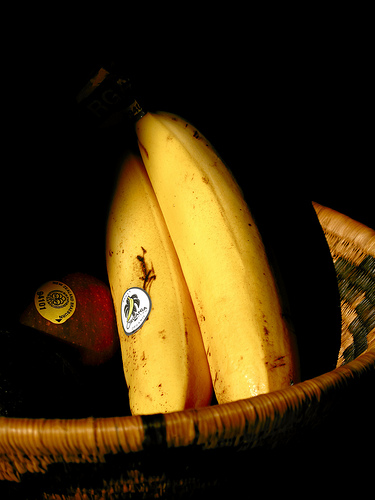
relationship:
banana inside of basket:
[107, 148, 212, 413] [15, 187, 372, 498]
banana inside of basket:
[107, 164, 197, 414] [15, 187, 372, 498]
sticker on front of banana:
[118, 286, 150, 332] [107, 164, 197, 414]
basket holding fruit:
[15, 187, 372, 498] [25, 72, 291, 394]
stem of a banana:
[86, 67, 153, 121] [107, 148, 212, 413]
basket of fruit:
[15, 187, 372, 498] [25, 72, 291, 394]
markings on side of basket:
[320, 236, 373, 366] [15, 187, 372, 498]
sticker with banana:
[118, 286, 150, 332] [107, 164, 197, 414]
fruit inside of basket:
[25, 72, 291, 394] [15, 187, 372, 498]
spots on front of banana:
[135, 245, 160, 300] [107, 164, 197, 414]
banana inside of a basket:
[107, 148, 212, 413] [15, 187, 372, 498]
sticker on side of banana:
[118, 286, 150, 332] [107, 164, 197, 414]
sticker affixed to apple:
[33, 280, 74, 325] [19, 272, 111, 370]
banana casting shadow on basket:
[107, 148, 212, 413] [15, 187, 372, 498]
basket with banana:
[15, 187, 372, 498] [107, 148, 212, 413]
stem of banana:
[86, 67, 153, 121] [107, 148, 212, 413]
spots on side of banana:
[135, 245, 160, 300] [107, 148, 212, 413]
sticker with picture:
[118, 286, 150, 332] [122, 297, 140, 319]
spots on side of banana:
[135, 245, 160, 300] [107, 164, 197, 414]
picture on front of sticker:
[122, 297, 140, 319] [118, 286, 150, 332]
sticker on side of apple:
[33, 280, 74, 325] [19, 272, 111, 370]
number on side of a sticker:
[37, 288, 45, 308] [33, 280, 74, 325]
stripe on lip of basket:
[129, 411, 180, 450] [15, 187, 372, 498]